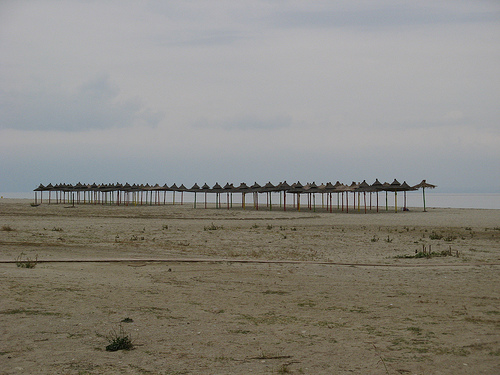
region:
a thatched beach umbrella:
[411, 176, 433, 211]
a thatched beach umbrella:
[396, 182, 414, 208]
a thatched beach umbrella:
[385, 179, 402, 209]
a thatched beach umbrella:
[380, 180, 389, 207]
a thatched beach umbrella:
[368, 176, 385, 210]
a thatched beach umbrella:
[357, 177, 371, 210]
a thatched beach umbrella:
[348, 180, 358, 212]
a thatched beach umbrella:
[337, 180, 352, 210]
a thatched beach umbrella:
[323, 181, 334, 210]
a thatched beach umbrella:
[309, 180, 325, 207]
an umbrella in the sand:
[412, 175, 442, 214]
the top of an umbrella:
[413, 177, 442, 192]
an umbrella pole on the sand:
[418, 185, 429, 215]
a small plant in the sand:
[98, 317, 148, 367]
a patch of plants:
[394, 242, 474, 269]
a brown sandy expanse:
[1, 195, 496, 373]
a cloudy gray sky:
[1, 0, 498, 209]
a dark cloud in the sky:
[0, 70, 174, 142]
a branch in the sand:
[366, 336, 405, 373]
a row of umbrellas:
[1, 175, 498, 215]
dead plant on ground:
[102, 326, 147, 363]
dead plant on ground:
[87, 314, 136, 355]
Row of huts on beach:
[27, 172, 445, 219]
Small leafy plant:
[99, 314, 143, 368]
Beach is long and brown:
[17, 212, 497, 369]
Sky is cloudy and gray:
[4, 47, 494, 212]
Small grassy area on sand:
[268, 286, 472, 362]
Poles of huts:
[33, 192, 434, 205]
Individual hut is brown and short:
[409, 165, 438, 210]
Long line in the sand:
[21, 253, 498, 273]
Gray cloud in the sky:
[23, 80, 160, 137]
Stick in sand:
[251, 352, 300, 362]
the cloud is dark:
[138, 3, 488, 138]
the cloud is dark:
[88, 45, 369, 171]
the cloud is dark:
[165, 110, 375, 241]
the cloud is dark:
[202, 70, 415, 166]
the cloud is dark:
[170, 61, 350, 208]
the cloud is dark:
[145, 17, 306, 90]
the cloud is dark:
[150, 46, 293, 76]